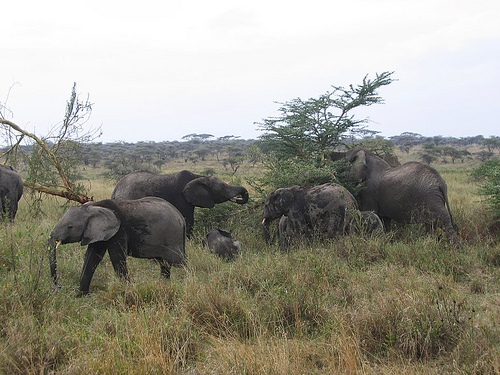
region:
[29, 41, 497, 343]
elephants standing in a field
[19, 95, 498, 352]
elephants standing in the grass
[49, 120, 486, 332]
elephants standing in tall grass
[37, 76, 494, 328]
elephants walking throught the grass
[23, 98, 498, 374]
elephants walking through the tall grass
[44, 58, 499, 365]
elephants standing by a tree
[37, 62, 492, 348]
an area with elephants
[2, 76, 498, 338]
an area of tall grass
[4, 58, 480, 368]
a field with elephants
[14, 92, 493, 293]
a field of tall grass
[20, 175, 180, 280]
the elephant in the wild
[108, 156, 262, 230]
the elephant in the wild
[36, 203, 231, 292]
the elephant in the wild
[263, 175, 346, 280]
the elephant in the wild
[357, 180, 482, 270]
the elephant in the wild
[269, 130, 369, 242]
the elephant in the wild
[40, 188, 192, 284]
the elephant is gray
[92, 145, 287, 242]
the elephant is gray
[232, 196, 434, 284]
the elephant is gray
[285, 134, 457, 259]
the elephant is gray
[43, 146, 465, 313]
herd of elephants in brush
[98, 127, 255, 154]
horizon line of trees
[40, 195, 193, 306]
gray elephant with tusks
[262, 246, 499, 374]
tall grass in a field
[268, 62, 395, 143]
tree branches with green foliage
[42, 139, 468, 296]
elephants in tall grass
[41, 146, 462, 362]
grassy plain with elephants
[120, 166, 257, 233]
elephant with trunk curled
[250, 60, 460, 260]
elephants under a tree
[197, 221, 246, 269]
baby elephant in long vegatation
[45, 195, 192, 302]
the elephant is facing left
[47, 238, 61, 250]
the elephant has tusks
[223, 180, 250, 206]
the elephant has his trunk curved in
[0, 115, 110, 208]
a tree has fallen to the ground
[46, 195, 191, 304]
the elephant is grey in color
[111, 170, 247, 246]
the elephant is grey in color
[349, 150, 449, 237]
the elephant is grey in color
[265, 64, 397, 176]
a large tree is behind the elephant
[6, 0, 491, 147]
the day is overcast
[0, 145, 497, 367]
the field is full of tall grass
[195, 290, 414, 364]
Grass in the photo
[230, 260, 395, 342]
Long grass in the photo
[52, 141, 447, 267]
Elephants in the savannah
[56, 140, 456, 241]
Elephants grazing in the field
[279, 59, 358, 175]
A tree in the photo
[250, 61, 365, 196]
A thorny tree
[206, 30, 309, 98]
Clouds in the photo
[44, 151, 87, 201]
A tree trunk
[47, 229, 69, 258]
An elephant trunk in the photo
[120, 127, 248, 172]
Thickets in the photo